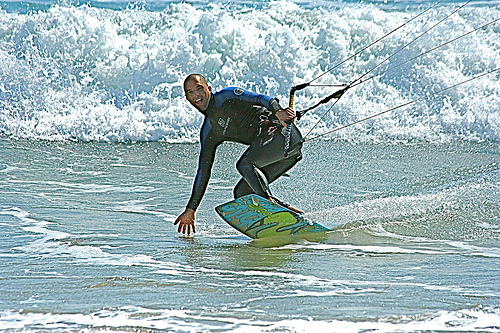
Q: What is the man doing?
A: Surfing.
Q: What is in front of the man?
A: A small trail of white waves.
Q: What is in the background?
A: A large wave crashing to shore.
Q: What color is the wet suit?
A: Blue and black.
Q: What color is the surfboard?
A: Green and blue.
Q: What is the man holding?
A: Black cords.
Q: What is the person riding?
A: A wakeboard.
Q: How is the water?
A: Clear.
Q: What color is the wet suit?
A: Black and blue.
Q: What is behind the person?
A: Waves.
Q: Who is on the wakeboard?
A: The person.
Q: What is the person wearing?
A: A wet suit.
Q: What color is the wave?
A: White.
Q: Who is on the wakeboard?
A: A man.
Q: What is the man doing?
A: Windsurfing.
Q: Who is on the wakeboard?
A: A man in a wetsuit.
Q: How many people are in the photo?
A: 1.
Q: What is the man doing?
A: Windsurfing.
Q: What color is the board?
A: Blue and green.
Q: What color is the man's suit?
A: Black and blue.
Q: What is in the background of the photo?
A: Wave.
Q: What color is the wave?
A: White.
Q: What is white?
A: Waves.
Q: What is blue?
A: Water.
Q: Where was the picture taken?
A: At the beach.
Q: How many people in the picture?
A: One.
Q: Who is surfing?
A: Man.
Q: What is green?
A: Surfboard.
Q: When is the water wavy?
A: Now.